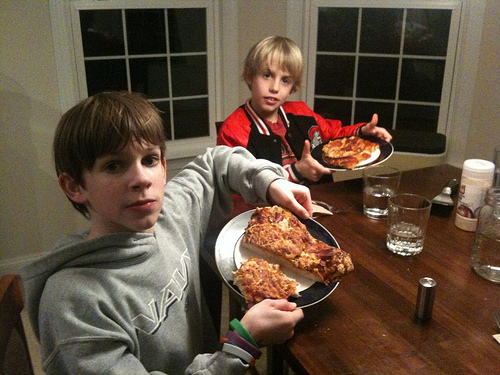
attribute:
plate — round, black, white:
[310, 135, 393, 173]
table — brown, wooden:
[190, 162, 496, 375]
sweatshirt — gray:
[19, 144, 289, 375]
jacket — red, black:
[218, 96, 364, 208]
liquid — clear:
[391, 223, 422, 244]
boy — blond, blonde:
[215, 35, 390, 217]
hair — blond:
[241, 34, 304, 96]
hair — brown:
[51, 91, 166, 219]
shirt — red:
[258, 109, 305, 167]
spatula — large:
[424, 176, 459, 218]